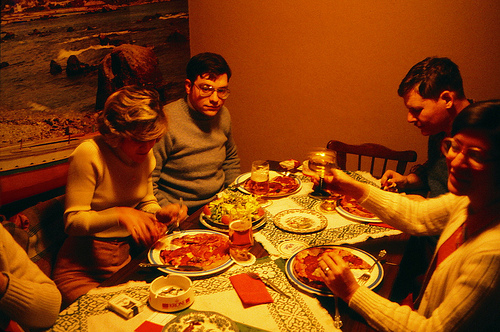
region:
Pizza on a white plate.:
[150, 220, 247, 285]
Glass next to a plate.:
[225, 169, 282, 205]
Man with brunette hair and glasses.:
[170, 35, 243, 130]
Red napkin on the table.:
[224, 265, 276, 313]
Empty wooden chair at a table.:
[320, 125, 445, 205]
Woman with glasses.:
[438, 125, 496, 197]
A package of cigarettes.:
[94, 285, 156, 327]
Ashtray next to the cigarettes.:
[136, 264, 203, 327]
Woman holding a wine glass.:
[295, 131, 361, 205]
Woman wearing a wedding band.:
[310, 255, 352, 290]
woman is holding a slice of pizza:
[130, 209, 169, 244]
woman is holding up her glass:
[303, 142, 343, 210]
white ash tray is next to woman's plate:
[146, 271, 198, 309]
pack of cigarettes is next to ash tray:
[104, 287, 146, 321]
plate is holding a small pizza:
[158, 224, 233, 276]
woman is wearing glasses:
[436, 134, 493, 179]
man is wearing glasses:
[192, 78, 233, 104]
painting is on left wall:
[1, 0, 197, 178]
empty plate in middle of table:
[275, 201, 328, 240]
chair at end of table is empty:
[312, 126, 421, 185]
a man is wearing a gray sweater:
[150, 51, 241, 207]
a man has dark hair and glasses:
[176, 50, 231, 120]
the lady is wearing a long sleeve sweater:
[63, 131, 159, 236]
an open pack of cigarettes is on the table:
[103, 290, 143, 320]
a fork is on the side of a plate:
[283, 238, 384, 301]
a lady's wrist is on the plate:
[310, 245, 382, 302]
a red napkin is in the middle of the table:
[227, 268, 272, 309]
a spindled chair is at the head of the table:
[320, 135, 416, 201]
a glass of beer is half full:
[246, 155, 272, 205]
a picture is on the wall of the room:
[4, 2, 194, 154]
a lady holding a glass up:
[303, 126, 493, 221]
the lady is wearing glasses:
[440, 100, 498, 196]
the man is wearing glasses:
[180, 50, 231, 117]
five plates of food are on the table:
[145, 165, 393, 300]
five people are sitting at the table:
[5, 50, 487, 323]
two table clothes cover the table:
[45, 166, 492, 327]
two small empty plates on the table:
[165, 210, 323, 330]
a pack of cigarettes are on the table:
[106, 291, 142, 316]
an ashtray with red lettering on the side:
[142, 272, 194, 310]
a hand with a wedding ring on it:
[310, 249, 361, 301]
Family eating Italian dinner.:
[62, 47, 494, 330]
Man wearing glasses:
[188, 47, 233, 114]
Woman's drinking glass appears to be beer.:
[225, 213, 257, 263]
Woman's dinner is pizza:
[281, 242, 389, 302]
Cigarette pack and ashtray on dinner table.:
[104, 268, 196, 319]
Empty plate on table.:
[273, 205, 328, 236]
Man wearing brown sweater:
[151, 98, 241, 205]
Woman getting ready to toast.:
[297, 147, 349, 203]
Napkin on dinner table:
[227, 267, 273, 308]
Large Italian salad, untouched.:
[196, 187, 268, 236]